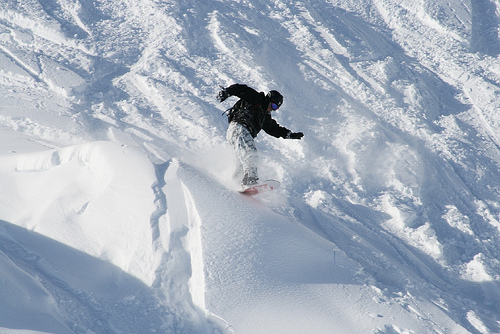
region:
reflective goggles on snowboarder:
[272, 101, 280, 113]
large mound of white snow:
[19, 144, 246, 294]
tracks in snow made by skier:
[0, 43, 62, 98]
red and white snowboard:
[232, 176, 289, 201]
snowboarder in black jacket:
[222, 75, 294, 143]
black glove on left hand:
[289, 130, 306, 142]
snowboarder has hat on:
[267, 89, 287, 108]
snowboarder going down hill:
[214, 77, 307, 201]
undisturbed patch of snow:
[211, 209, 273, 305]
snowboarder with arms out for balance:
[216, 78, 308, 202]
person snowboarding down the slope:
[196, 63, 307, 223]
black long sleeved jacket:
[194, 71, 309, 150]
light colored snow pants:
[218, 121, 265, 190]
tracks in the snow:
[153, 167, 206, 308]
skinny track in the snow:
[3, 46, 40, 81]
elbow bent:
[233, 78, 252, 106]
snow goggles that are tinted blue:
[266, 99, 280, 113]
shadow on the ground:
[3, 221, 140, 332]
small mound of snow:
[12, 141, 329, 318]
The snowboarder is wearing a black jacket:
[204, 68, 303, 232]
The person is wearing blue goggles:
[258, 83, 288, 113]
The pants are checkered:
[208, 113, 275, 196]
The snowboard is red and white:
[220, 161, 300, 220]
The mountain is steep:
[49, 8, 472, 283]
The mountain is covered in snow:
[35, 8, 456, 320]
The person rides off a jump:
[205, 63, 307, 215]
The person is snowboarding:
[211, 63, 308, 211]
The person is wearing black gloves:
[277, 124, 309, 146]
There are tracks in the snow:
[125, 137, 228, 306]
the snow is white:
[238, 218, 332, 328]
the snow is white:
[252, 239, 317, 292]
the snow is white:
[257, 211, 300, 277]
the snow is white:
[266, 231, 308, 311]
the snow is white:
[249, 250, 302, 325]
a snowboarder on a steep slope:
[14, 6, 493, 323]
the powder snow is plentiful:
[24, 9, 499, 311]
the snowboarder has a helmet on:
[262, 87, 286, 114]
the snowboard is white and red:
[234, 179, 285, 199]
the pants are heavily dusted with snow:
[223, 120, 262, 185]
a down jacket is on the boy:
[224, 80, 296, 142]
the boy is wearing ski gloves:
[213, 87, 305, 148]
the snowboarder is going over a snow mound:
[201, 75, 310, 251]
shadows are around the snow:
[14, 5, 493, 325]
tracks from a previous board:
[126, 140, 226, 332]